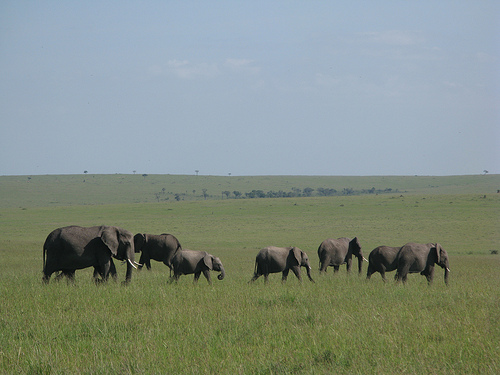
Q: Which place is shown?
A: It is a field.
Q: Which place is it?
A: It is a field.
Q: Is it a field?
A: Yes, it is a field.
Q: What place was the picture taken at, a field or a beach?
A: It was taken at a field.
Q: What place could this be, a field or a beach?
A: It is a field.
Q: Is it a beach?
A: No, it is a field.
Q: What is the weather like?
A: It is clear.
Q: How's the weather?
A: It is clear.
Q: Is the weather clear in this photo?
A: Yes, it is clear.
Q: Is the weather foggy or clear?
A: It is clear.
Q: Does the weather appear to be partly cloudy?
A: No, it is clear.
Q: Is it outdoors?
A: Yes, it is outdoors.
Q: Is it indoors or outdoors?
A: It is outdoors.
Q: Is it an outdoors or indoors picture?
A: It is outdoors.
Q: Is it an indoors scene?
A: No, it is outdoors.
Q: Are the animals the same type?
A: Yes, all the animals are elephants.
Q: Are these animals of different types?
A: No, all the animals are elephants.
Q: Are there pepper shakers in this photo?
A: No, there are no pepper shakers.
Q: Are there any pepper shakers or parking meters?
A: No, there are no pepper shakers or parking meters.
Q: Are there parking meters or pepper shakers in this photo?
A: No, there are no pepper shakers or parking meters.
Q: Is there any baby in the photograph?
A: Yes, there is a baby.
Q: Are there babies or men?
A: Yes, there is a baby.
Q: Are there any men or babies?
A: Yes, there is a baby.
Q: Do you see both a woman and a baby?
A: No, there is a baby but no women.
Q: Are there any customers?
A: No, there are no customers.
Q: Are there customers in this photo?
A: No, there are no customers.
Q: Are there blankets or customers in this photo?
A: No, there are no customers or blankets.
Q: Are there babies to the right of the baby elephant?
A: Yes, there is a baby to the right of the elephant.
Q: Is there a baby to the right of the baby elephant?
A: Yes, there is a baby to the right of the elephant.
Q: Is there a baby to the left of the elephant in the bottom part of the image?
A: No, the baby is to the right of the elephant.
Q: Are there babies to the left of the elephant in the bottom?
A: No, the baby is to the right of the elephant.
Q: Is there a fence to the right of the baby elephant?
A: No, there is a baby to the right of the elephant.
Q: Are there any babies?
A: Yes, there is a baby.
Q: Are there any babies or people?
A: Yes, there is a baby.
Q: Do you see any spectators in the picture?
A: No, there are no spectators.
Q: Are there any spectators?
A: No, there are no spectators.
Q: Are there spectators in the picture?
A: No, there are no spectators.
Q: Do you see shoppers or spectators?
A: No, there are no spectators or shoppers.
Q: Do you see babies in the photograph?
A: Yes, there is a baby.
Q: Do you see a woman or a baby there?
A: Yes, there is a baby.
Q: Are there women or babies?
A: Yes, there is a baby.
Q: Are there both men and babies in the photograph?
A: No, there is a baby but no men.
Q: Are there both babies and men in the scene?
A: No, there is a baby but no men.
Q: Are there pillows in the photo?
A: No, there are no pillows.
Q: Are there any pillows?
A: No, there are no pillows.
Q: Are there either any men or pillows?
A: No, there are no pillows or men.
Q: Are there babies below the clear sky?
A: Yes, there is a baby below the sky.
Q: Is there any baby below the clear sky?
A: Yes, there is a baby below the sky.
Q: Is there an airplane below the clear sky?
A: No, there is a baby below the sky.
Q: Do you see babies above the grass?
A: Yes, there is a baby above the grass.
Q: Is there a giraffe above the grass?
A: No, there is a baby above the grass.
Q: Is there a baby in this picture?
A: Yes, there is a baby.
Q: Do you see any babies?
A: Yes, there is a baby.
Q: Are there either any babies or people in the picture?
A: Yes, there is a baby.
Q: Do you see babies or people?
A: Yes, there is a baby.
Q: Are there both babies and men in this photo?
A: No, there is a baby but no men.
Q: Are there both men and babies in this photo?
A: No, there is a baby but no men.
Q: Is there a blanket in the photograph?
A: No, there are no blankets.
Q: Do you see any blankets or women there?
A: No, there are no blankets or women.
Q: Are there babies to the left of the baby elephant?
A: No, the baby is to the right of the elephant.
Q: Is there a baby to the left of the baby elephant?
A: No, the baby is to the right of the elephant.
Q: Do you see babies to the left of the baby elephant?
A: No, the baby is to the right of the elephant.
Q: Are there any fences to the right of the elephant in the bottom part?
A: No, there is a baby to the right of the elephant.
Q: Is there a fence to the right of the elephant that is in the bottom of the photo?
A: No, there is a baby to the right of the elephant.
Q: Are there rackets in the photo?
A: No, there are no rackets.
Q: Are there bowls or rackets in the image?
A: No, there are no rackets or bowls.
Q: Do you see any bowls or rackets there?
A: No, there are no rackets or bowls.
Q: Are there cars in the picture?
A: No, there are no cars.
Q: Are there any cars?
A: No, there are no cars.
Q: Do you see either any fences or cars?
A: No, there are no cars or fences.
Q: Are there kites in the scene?
A: No, there are no kites.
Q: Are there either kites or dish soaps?
A: No, there are no kites or dish soaps.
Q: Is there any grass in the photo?
A: Yes, there is grass.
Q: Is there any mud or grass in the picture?
A: Yes, there is grass.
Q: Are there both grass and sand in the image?
A: No, there is grass but no sand.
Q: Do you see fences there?
A: No, there are no fences.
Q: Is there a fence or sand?
A: No, there are no fences or sand.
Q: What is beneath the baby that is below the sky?
A: The grass is beneath the baby.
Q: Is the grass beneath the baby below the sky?
A: Yes, the grass is beneath the baby.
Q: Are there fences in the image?
A: No, there are no fences.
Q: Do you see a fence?
A: No, there are no fences.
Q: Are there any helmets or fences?
A: No, there are no fences or helmets.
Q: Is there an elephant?
A: Yes, there is an elephant.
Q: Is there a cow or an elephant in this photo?
A: Yes, there is an elephant.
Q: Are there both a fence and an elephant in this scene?
A: No, there is an elephant but no fences.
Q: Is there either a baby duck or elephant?
A: Yes, there is a baby elephant.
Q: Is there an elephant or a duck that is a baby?
A: Yes, the elephant is a baby.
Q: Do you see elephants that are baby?
A: Yes, there is a baby elephant.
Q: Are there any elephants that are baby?
A: Yes, there is an elephant that is a baby.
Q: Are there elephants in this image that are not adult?
A: Yes, there is an baby elephant.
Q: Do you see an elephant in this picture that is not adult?
A: Yes, there is an baby elephant.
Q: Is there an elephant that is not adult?
A: Yes, there is an baby elephant.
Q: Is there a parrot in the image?
A: No, there are no parrots.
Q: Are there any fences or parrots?
A: No, there are no parrots or fences.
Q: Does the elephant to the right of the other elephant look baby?
A: Yes, the elephant is a baby.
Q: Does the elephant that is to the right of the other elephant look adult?
A: No, the elephant is a baby.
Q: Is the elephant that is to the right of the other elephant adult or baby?
A: The elephant is a baby.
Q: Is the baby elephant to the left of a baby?
A: Yes, the elephant is to the left of a baby.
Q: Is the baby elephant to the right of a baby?
A: No, the elephant is to the left of a baby.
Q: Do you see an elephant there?
A: Yes, there is an elephant.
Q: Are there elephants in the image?
A: Yes, there is an elephant.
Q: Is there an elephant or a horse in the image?
A: Yes, there is an elephant.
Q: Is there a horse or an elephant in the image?
A: Yes, there is an elephant.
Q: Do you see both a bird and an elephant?
A: No, there is an elephant but no birds.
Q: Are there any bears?
A: No, there are no bears.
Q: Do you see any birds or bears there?
A: No, there are no bears or birds.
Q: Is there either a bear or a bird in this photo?
A: No, there are no bears or birds.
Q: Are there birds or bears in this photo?
A: No, there are no bears or birds.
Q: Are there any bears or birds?
A: No, there are no bears or birds.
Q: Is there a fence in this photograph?
A: No, there are no fences.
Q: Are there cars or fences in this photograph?
A: No, there are no fences or cars.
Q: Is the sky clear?
A: Yes, the sky is clear.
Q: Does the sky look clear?
A: Yes, the sky is clear.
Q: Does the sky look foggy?
A: No, the sky is clear.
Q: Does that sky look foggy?
A: No, the sky is clear.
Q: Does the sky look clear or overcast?
A: The sky is clear.